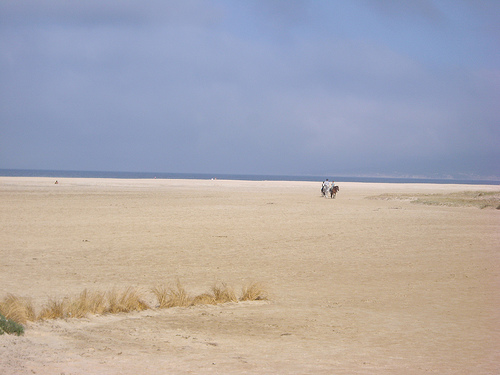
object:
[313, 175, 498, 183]
planter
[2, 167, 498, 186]
water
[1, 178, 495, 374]
ground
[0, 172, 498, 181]
ocean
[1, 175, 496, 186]
shore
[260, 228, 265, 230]
sand grain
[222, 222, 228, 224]
sand grain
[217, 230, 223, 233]
sand grain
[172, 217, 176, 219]
sand grain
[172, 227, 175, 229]
sand grain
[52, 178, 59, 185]
speck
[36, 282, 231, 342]
grass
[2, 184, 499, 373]
sand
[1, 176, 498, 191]
shoreline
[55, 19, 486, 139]
clear sky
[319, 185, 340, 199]
horses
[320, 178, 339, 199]
person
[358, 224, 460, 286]
dirt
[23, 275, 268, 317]
plants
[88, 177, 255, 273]
beach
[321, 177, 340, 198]
people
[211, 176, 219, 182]
street sign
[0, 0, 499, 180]
sky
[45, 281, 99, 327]
grass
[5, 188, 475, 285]
beach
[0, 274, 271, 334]
grass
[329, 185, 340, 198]
horse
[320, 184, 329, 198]
horse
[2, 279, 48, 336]
grass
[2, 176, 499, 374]
beach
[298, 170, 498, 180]
mountains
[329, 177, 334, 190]
person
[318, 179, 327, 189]
person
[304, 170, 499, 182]
land